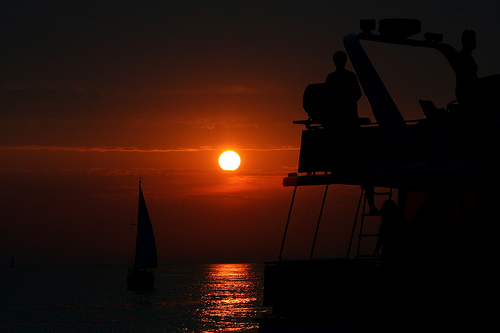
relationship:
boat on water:
[126, 179, 171, 311] [0, 260, 499, 332]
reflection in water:
[193, 261, 273, 331] [0, 260, 499, 332]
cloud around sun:
[4, 88, 300, 169] [212, 145, 245, 178]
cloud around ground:
[4, 88, 300, 169] [411, 145, 459, 196]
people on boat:
[310, 47, 364, 143] [274, 16, 499, 331]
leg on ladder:
[364, 189, 383, 215] [342, 184, 387, 314]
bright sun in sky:
[218, 150, 241, 171] [9, 4, 492, 269]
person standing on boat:
[450, 30, 480, 105] [263, 14, 495, 311]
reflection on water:
[193, 261, 272, 333] [131, 248, 324, 332]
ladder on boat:
[346, 184, 394, 259] [253, 9, 498, 330]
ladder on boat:
[349, 179, 397, 269] [274, 16, 499, 331]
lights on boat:
[356, 13, 445, 45] [266, 27, 498, 274]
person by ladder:
[372, 194, 399, 255] [345, 182, 408, 259]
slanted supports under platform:
[270, 172, 372, 261] [285, 140, 494, 190]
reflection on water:
[193, 261, 272, 333] [1, 254, 326, 330]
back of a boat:
[264, 117, 407, 329] [257, 44, 497, 317]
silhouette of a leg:
[363, 181, 377, 216] [364, 186, 375, 208]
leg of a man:
[364, 186, 375, 208] [357, 168, 382, 218]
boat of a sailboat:
[124, 169, 161, 295] [104, 154, 186, 295]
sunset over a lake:
[4, 0, 496, 261] [2, 264, 498, 327]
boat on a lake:
[124, 169, 161, 295] [0, 257, 498, 327]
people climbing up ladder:
[315, 49, 364, 128] [258, 169, 408, 277]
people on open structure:
[315, 49, 364, 128] [288, 40, 484, 185]